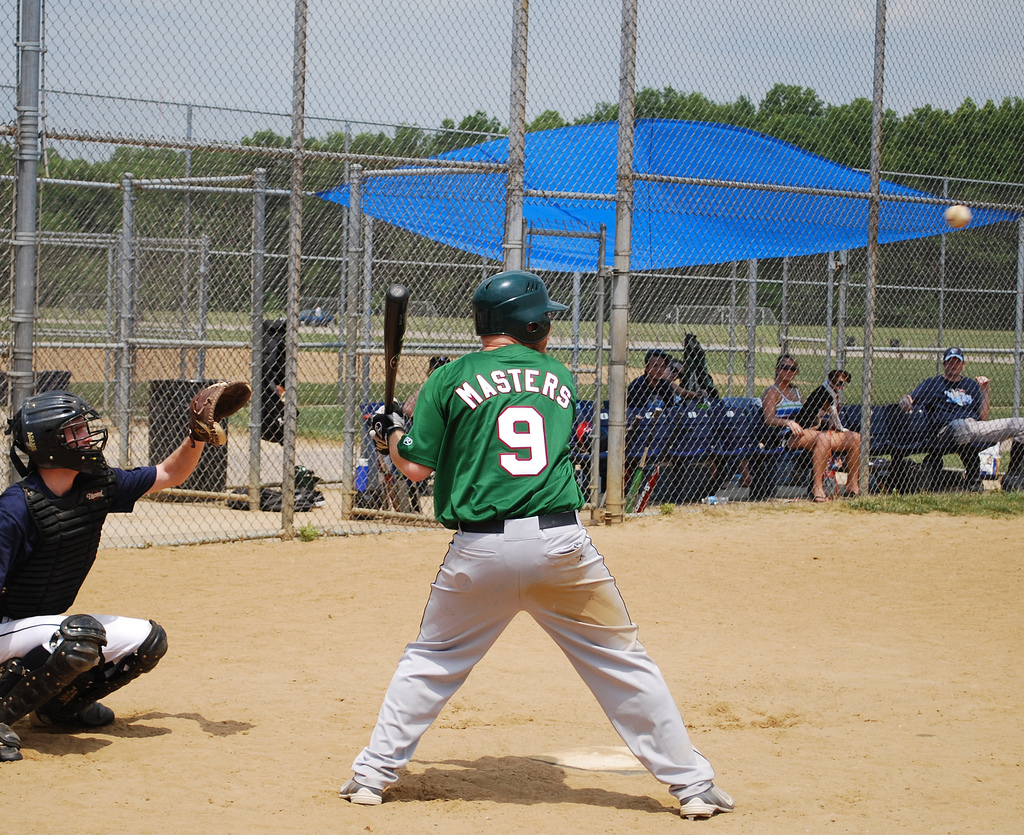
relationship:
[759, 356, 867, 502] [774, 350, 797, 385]
people has face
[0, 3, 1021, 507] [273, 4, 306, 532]
fence has pole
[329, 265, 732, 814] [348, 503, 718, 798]
batter has pants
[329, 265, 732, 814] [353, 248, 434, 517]
batter holding bat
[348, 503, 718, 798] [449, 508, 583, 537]
pants with belt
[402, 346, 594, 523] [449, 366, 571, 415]
jersey with name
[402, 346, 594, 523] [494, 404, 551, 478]
jersey with number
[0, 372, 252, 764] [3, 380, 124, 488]
catcher wearing helmet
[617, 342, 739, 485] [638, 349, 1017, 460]
people sitting in chairs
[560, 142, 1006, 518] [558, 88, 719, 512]
fencing attached to posts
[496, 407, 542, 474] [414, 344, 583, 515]
number on shirt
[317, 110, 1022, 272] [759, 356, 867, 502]
tarp over people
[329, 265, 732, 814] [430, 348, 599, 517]
batter wearing shirt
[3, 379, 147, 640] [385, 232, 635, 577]
catcher squatting behind batter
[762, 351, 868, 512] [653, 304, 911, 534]
person watching game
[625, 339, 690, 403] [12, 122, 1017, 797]
person watching game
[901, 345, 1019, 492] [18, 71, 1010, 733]
people watching game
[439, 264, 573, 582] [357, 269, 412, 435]
batter holding bat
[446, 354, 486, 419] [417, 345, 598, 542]
letter on jersey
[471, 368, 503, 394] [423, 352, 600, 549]
letter on jersey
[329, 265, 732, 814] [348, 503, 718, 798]
batter wearing pants